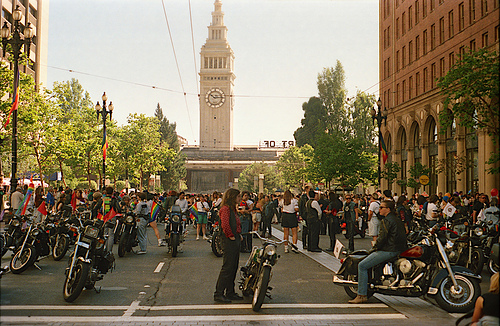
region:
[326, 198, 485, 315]
a man sitting on a motorcycle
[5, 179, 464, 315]
motorcyles are in the road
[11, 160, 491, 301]
a crowd gathers in the street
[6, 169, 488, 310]
people are in the road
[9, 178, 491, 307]
the road is full of both people and motorcycles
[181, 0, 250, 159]
a clock tower is at the end of the road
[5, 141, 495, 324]
an event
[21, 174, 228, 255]
people are holding flags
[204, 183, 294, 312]
a woman in red stands next to a motorcycle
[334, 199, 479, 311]
a man in a black leather jacket sits on the motorcycle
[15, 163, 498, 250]
People are on the street.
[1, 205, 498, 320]
Motorcycles are on the street.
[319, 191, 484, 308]
A man sits on the motorcycle.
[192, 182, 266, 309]
A woman is standing.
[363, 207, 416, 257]
The man wears a black jacket.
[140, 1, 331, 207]
A building is in the background.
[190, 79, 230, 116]
A clock is on the building.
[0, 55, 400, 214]
Trees are next to the street.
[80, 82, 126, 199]
Street lights line the street.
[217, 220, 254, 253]
The woman's hands are in her pockets.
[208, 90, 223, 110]
clock on the tower.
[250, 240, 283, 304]
motorcycle on the street.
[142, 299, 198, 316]
white lines painted on street.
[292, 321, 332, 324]
bricks on the sidewalk.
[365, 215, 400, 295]
man sitting on motorcycle.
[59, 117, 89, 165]
green leaves on the trees.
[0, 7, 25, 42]
street lights on top of pole.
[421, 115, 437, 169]
arched windows on building.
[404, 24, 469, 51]
building facade above crowd.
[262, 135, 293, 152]
letters on top of building.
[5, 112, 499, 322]
A bunch of people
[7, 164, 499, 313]
Motorcycles parked on a street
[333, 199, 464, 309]
A man in a leather jacket sitting on a motorcycle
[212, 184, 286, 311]
A woman in red and black standing beside a motorcycle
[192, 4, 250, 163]
A white tower with a clock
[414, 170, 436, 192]
A round yellow sign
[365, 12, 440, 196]
A light pole beside a building with arches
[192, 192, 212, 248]
A person wearing green and blue shorts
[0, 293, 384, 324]
Solid white lines on a street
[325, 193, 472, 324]
A man sitting on a motorcycle wearing sunglasses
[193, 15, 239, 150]
this is a building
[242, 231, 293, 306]
this is a motorcycle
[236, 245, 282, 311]
the motorcycle is parked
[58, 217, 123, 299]
this motorcycle is big in size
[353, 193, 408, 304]
the man is sitted on the seat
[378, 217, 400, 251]
the jacket is black in color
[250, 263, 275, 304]
the wheel is big in size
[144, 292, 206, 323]
white strips are on the road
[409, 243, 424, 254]
the motorcycle is red in color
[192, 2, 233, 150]
the building is cream in color